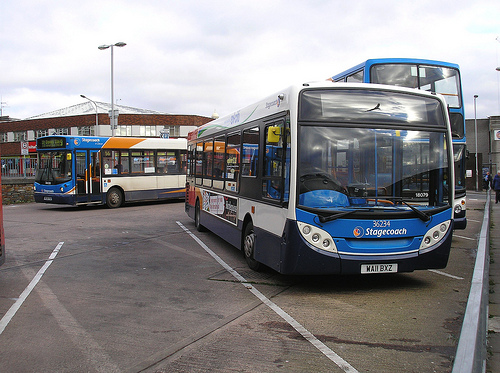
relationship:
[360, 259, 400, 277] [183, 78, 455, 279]
license plate on bus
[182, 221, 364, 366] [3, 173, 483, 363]
line on lot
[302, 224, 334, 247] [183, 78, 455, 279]
light on bus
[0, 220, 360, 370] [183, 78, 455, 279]
parking slot for bus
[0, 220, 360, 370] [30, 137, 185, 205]
parking slot for bus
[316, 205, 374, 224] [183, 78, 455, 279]
windshield wiper on bus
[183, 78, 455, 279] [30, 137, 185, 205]
bus is across from white bus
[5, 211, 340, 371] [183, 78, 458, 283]
space for bus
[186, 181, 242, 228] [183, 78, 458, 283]
advertisement on bus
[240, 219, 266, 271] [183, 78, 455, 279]
wheel on bus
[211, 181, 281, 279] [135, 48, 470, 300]
wheel on bus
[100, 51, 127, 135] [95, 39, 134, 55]
metal pole with fixtures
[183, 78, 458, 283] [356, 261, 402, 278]
bus front license plate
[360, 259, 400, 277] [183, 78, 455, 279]
license plate of bus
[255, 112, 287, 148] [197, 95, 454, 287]
mirror of bus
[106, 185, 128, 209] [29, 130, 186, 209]
wheel of a bus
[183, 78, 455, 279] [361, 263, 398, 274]
bus registration number plate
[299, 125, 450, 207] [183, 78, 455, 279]
window of bus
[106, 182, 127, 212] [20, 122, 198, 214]
wheel on bus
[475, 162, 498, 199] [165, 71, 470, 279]
people waiting for bus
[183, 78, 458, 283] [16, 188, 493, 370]
bus in lot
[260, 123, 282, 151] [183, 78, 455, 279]
mirror on bus